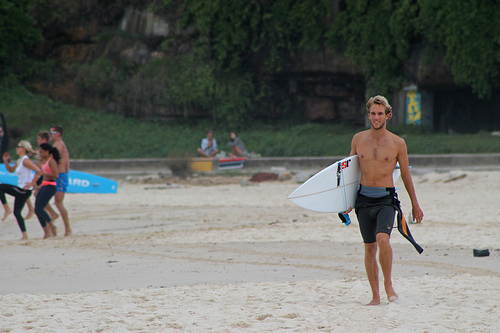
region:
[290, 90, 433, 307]
A man carrying a surfboard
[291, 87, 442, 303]
A man wearing a wetsuit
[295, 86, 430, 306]
A man walking in the sand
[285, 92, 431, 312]
A man walking on the beach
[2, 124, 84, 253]
A group of people on the beach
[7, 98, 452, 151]
A grassy area near the beach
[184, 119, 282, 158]
People sitting in the grass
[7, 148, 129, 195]
A blue surfboard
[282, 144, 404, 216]
A man carrying a white surfboard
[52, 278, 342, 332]
A sandy beach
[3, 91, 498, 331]
The beach is sandy.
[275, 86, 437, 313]
The man is carrying a surfboard.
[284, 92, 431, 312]
The man is barefoot.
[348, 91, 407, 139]
The man is smiling.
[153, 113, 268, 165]
People are sitting in the grass.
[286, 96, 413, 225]
The surfboard is white.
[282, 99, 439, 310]
The man is wearing a wetsuit.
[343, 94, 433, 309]
The top of the wetsuit is pulled down.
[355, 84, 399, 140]
The man has short hair.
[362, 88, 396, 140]
The man has blonde hair.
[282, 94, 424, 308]
Man walks with surfboard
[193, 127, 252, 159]
Pair sit along beach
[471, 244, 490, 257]
Garbage on the beach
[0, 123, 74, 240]
Group runs on the beach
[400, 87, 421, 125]
Graffiti near the beach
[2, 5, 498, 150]
Lush and rocky landscape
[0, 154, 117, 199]
Light blue and white surfboard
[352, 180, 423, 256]
Gray colored swimsuit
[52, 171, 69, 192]
Blue colored swim trunks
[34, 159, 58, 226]
Pink and gray yoga attire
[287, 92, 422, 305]
a male surfer on beach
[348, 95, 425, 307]
a shirtless man on beach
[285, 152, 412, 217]
a white surfboard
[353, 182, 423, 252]
black surfing clothes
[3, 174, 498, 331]
a light brown sandy beach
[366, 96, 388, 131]
a man's bearded face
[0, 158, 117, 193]
a light blue surfboard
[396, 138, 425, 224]
a man's left arm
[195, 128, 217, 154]
a person sitting in grassy area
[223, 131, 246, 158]
a person sitting in grassy area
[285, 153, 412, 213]
A white surf board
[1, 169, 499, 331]
A sandy beach.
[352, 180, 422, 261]
A black wet suit.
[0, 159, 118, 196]
A long light blue surf board.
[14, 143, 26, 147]
A pair of sun glasses.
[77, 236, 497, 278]
A long track in the sand.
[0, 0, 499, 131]
Large rocks in background.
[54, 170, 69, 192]
A blue pair of shorts.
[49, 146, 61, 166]
A long black pony tail.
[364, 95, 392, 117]
Short blond hair.